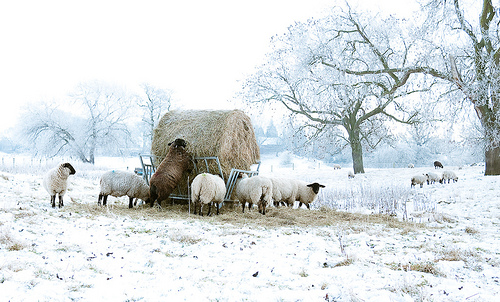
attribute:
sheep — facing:
[41, 157, 78, 209]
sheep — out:
[44, 160, 76, 207]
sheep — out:
[148, 135, 193, 206]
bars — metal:
[122, 149, 260, 211]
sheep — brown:
[147, 137, 199, 208]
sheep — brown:
[143, 132, 196, 214]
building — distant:
[93, 72, 307, 219]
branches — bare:
[254, 20, 434, 130]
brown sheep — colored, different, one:
[147, 135, 197, 202]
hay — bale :
[143, 102, 271, 208]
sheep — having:
[18, 160, 356, 200]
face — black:
[58, 157, 75, 172]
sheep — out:
[98, 173, 151, 207]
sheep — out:
[192, 165, 227, 212]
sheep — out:
[235, 173, 271, 212]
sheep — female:
[42, 161, 459, 216]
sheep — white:
[179, 161, 237, 223]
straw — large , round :
[154, 111, 261, 177]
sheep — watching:
[37, 153, 86, 215]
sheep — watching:
[88, 158, 159, 221]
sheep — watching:
[174, 163, 234, 218]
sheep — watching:
[227, 166, 284, 220]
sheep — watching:
[283, 170, 336, 213]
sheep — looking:
[292, 176, 335, 213]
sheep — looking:
[266, 165, 304, 206]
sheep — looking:
[233, 167, 285, 214]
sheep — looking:
[185, 159, 233, 214]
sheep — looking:
[140, 133, 197, 216]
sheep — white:
[43, 163, 79, 211]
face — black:
[309, 181, 319, 195]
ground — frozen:
[201, 213, 434, 300]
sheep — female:
[189, 172, 225, 217]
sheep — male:
[149, 137, 189, 203]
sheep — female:
[98, 175, 149, 205]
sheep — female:
[42, 161, 73, 203]